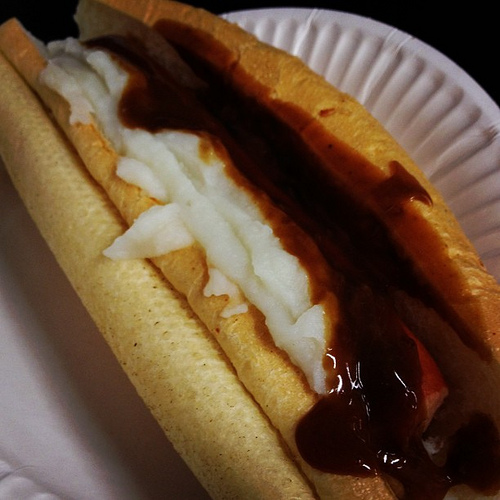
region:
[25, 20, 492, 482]
a hot dog on a bun on a paper plate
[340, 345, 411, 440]
some ketchup sauce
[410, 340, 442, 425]
some hot dog meat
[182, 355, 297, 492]
the lower half of a bread bun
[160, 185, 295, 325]
some white melted cheese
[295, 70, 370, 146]
the top half of a bun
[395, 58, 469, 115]
a paper plate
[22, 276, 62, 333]
a shadow of the hot dog bun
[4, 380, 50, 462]
the color white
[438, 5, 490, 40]
a black background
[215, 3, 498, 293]
corner of the white paper plate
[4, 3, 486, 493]
white paper plates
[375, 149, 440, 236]
brown sauce on a bun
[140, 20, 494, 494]
brown sauce on the hot dog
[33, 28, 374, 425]
white topping on a hot dog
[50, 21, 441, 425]
a hot dog in a bun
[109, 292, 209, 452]
brown spots on the bun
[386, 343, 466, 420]
barbeque sauce on the hot dog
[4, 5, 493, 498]
a hot dog in a bun on a white plate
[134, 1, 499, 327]
top of a hot dog bun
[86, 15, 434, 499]
BBQ sauce on a hot dog.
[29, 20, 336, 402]
onions on a hot dog.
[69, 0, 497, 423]
the left side of a bun.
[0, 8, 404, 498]
A right side of a bun.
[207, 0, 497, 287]
The right side of a paper plate.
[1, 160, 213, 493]
the left side of a paper plate.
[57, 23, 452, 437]
a hot dog on a bun.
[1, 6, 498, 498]
a hot dog on a paper plate.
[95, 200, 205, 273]
a piece of an onion.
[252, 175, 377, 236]
BBQ sauce on a hot dog.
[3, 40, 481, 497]
Hot dog on a bun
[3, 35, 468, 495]
Hot dog with mashed potatoes and gravy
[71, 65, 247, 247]
Potatoes on a hot dog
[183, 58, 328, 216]
Gravy on a hot dog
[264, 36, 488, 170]
A paper plate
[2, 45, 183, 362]
A hot dog bun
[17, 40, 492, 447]
A hot dog on a paper plate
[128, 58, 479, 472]
A brat on a bun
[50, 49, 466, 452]
Potatoes and gravy on a brat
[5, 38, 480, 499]
A brat on a paper plate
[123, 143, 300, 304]
onions on a hot dog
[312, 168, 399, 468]
brown sauce on a hot dog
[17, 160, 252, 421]
hot dog bun on a plate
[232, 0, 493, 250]
outer edge of a paper plate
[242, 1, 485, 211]
paper plate with ribs for sturdiness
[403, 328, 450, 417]
meat visible beneath the sauce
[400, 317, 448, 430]
meat visible below the sauce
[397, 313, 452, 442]
meat visible under the sauce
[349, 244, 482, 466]
sauce covering the meat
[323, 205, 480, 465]
dark brown sauce covering the meat